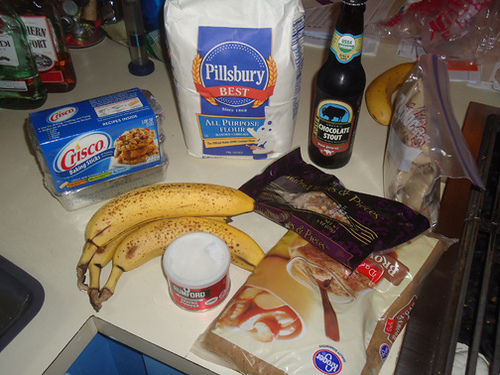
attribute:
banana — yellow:
[70, 177, 275, 278]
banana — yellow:
[98, 195, 260, 313]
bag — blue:
[163, 3, 307, 161]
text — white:
[204, 63, 269, 84]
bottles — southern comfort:
[1, 7, 84, 124]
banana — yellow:
[50, 151, 266, 228]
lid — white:
[147, 200, 256, 299]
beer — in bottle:
[304, 0, 370, 173]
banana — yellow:
[92, 216, 234, 266]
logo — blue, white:
[312, 347, 343, 372]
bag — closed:
[376, 47, 489, 235]